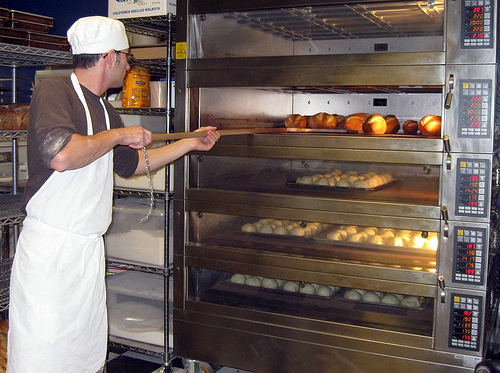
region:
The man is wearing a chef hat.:
[63, 16, 138, 57]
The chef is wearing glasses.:
[99, 37, 143, 67]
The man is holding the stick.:
[105, 117, 283, 148]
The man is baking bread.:
[21, 37, 462, 160]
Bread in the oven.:
[266, 88, 443, 143]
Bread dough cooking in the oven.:
[244, 150, 414, 202]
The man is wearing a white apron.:
[49, 116, 119, 360]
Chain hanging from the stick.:
[126, 133, 162, 237]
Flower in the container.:
[118, 210, 184, 256]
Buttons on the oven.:
[471, 70, 496, 148]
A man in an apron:
[4, 14, 219, 371]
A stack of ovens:
[186, 0, 498, 357]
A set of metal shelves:
[101, 12, 176, 368]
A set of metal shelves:
[0, 40, 75, 313]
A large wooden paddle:
[143, 124, 353, 144]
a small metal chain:
[139, 145, 157, 222]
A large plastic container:
[101, 195, 176, 265]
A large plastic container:
[107, 270, 174, 347]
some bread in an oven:
[278, 104, 442, 139]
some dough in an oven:
[296, 164, 398, 191]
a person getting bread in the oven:
[11, 11, 351, 371]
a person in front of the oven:
[8, 13, 225, 369]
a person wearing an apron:
[5, 11, 150, 371]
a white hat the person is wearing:
[63, 13, 132, 58]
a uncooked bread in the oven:
[287, 164, 401, 196]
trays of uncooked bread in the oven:
[233, 217, 438, 262]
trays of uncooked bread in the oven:
[210, 270, 429, 311]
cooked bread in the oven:
[281, 101, 441, 138]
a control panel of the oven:
[454, 77, 492, 153]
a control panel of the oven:
[445, 290, 481, 354]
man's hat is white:
[61, 8, 133, 62]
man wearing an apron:
[8, 78, 126, 370]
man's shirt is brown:
[16, 73, 141, 214]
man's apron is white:
[9, 72, 119, 370]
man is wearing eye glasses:
[93, 48, 137, 62]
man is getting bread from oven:
[2, 0, 496, 370]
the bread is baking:
[225, 167, 438, 315]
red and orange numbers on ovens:
[458, 1, 487, 346]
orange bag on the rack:
[123, 60, 153, 110]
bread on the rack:
[0, 99, 35, 127]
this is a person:
[22, 15, 165, 368]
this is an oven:
[185, 246, 486, 367]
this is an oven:
[190, 187, 487, 267]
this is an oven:
[191, 131, 489, 216]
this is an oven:
[195, 60, 498, 140]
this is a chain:
[143, 145, 156, 225]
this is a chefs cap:
[68, 7, 127, 51]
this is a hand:
[31, 85, 151, 168]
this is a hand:
[111, 109, 218, 180]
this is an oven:
[173, 5, 498, 372]